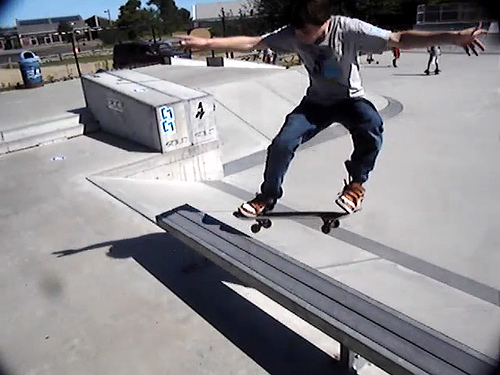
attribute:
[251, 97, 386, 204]
jeans — blue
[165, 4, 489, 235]
boy — wearing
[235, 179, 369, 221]
shoes — brown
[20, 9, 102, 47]
house — large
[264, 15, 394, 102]
shirt — gray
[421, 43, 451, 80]
person — skating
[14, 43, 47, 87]
cans — garbage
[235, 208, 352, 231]
skateboard — gray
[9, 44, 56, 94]
trash can — large, blue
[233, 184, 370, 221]
shoes — brown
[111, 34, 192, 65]
suv — black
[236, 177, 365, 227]
sneakers — brown, white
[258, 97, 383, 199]
jeans — blue